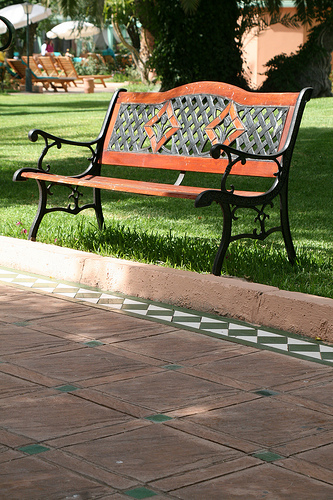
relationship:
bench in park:
[13, 79, 316, 278] [2, 2, 329, 499]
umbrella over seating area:
[46, 17, 101, 40] [53, 45, 108, 71]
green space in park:
[11, 98, 95, 129] [2, 2, 329, 499]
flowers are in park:
[108, 62, 147, 83] [2, 2, 329, 499]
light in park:
[47, 19, 126, 48] [2, 2, 329, 499]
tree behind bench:
[126, 3, 255, 91] [13, 79, 316, 278]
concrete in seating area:
[83, 83, 119, 92] [53, 45, 108, 71]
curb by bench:
[2, 234, 331, 337] [13, 79, 316, 278]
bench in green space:
[13, 79, 316, 278] [11, 98, 95, 129]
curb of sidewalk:
[2, 234, 331, 337] [11, 280, 328, 496]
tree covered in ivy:
[126, 3, 255, 91] [217, 16, 238, 71]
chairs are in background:
[8, 51, 114, 91] [8, 3, 134, 96]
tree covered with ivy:
[126, 3, 255, 91] [217, 16, 238, 71]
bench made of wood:
[13, 79, 316, 278] [108, 77, 305, 111]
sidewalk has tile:
[11, 280, 328, 496] [170, 312, 205, 329]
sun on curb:
[108, 25, 121, 49] [2, 234, 331, 337]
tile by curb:
[170, 312, 205, 329] [2, 234, 331, 337]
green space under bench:
[11, 98, 95, 129] [13, 79, 316, 278]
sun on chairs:
[108, 25, 121, 49] [8, 51, 114, 91]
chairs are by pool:
[8, 51, 114, 91] [95, 32, 124, 56]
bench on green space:
[13, 79, 316, 278] [11, 98, 95, 129]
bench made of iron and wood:
[13, 79, 316, 278] [253, 81, 313, 184]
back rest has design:
[94, 81, 295, 172] [136, 101, 189, 148]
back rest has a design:
[94, 81, 295, 172] [136, 101, 189, 148]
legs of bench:
[30, 215, 293, 262] [13, 79, 316, 278]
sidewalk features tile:
[11, 280, 328, 496] [170, 312, 205, 329]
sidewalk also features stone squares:
[11, 280, 328, 496] [38, 362, 274, 481]